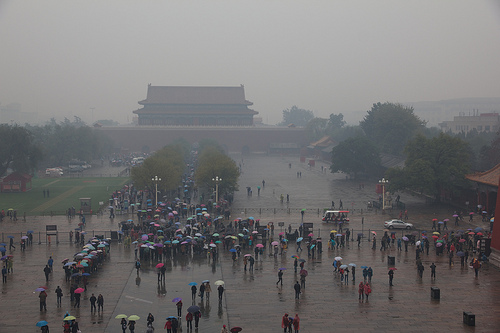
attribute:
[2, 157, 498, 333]
peope — standing, waiting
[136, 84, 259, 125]
building — asian style, large, temple, red, tall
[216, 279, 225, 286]
umbrellas — red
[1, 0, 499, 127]
sky — rainy, cloudy, overcast, grey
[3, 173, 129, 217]
lawn — green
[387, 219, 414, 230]
car — silver, white, small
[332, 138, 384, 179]
tree — green, tall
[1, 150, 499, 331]
ground — wet, brown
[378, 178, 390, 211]
post — tall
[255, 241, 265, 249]
umbrella — pink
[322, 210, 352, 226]
chair — tall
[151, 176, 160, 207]
pole — tall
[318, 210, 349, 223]
vehicle — red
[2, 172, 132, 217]
field — green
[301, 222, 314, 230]
sign — brown